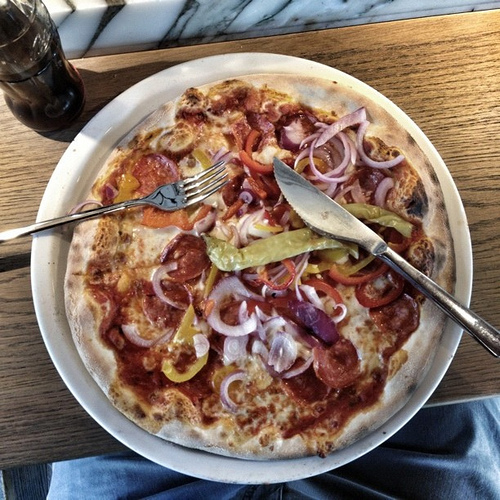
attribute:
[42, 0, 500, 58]
counter — marble, black, white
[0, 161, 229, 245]
fork — silver, metal, steel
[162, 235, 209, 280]
pepperoni — red, round, sliced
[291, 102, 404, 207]
onion — red, purple, sliced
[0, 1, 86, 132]
soda — dark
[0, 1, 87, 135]
bottle — glass, soda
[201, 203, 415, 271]
pepper — green, wrinkled, large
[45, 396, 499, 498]
jeans — blue, denim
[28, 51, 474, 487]
pan — white, round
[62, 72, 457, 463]
pizza — small, uncut, cooked, thin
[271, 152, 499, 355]
knife — metal, silver, serrated, steel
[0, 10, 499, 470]
table — brown, wooden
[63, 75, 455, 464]
food — pizza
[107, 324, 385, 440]
sauce — red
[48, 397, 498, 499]
cloth — blue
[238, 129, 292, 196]
peppers — red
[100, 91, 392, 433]
cheese — browned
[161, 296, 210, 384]
peppers — yellow